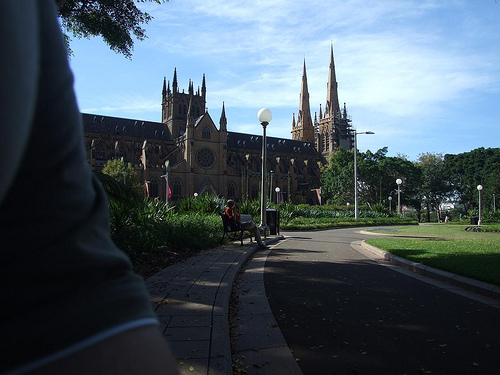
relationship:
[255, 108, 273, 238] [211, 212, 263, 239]
lamp next to bench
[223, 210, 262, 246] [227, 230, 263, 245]
bench has legs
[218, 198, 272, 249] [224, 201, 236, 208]
man has head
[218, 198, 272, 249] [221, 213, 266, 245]
man on bench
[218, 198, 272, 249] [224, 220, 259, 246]
man on bench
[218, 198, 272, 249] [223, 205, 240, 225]
man wearing shirt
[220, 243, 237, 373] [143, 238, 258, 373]
curb of sidewalk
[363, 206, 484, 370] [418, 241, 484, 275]
area has grass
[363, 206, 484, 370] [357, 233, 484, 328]
area has curb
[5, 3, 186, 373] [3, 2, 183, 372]
person wearing shirt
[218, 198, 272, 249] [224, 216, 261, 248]
man on bench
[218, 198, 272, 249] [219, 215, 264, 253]
man on bench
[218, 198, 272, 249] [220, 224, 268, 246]
man sitting down on bench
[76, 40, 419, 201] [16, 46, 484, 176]
building in distance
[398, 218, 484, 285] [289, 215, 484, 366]
grass near road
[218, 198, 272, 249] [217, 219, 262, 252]
man sitting on bench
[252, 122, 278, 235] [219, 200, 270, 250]
pole behind man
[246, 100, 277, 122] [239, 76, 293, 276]
lamp on pole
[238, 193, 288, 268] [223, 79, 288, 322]
bin near pole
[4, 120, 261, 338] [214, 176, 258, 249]
bushes behind man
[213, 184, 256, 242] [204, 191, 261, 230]
man has shirt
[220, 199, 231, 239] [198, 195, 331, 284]
arm of person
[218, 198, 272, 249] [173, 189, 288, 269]
man on bench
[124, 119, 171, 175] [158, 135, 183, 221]
flags on pole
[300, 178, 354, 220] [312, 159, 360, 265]
flag on pole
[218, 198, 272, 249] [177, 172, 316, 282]
man on bench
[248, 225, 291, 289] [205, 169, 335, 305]
legs of person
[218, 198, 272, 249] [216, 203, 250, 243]
man wearing shirt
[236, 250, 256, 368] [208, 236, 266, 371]
leaves along curb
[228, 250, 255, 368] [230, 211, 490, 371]
leaves scattered on pavement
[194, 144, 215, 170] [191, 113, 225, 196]
design inset into abbey